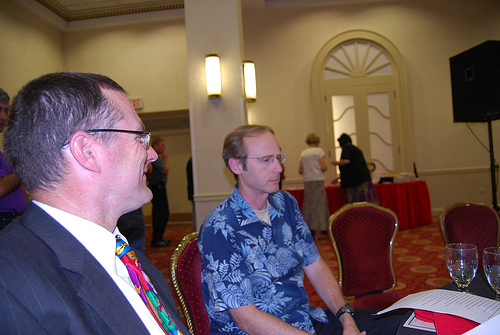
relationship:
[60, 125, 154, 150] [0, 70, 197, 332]
eyeglasses on man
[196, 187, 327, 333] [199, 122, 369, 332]
shirt on man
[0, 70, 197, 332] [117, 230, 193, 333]
man wearing tie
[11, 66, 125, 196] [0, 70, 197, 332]
hair on a man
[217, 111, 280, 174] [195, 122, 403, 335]
hair on a man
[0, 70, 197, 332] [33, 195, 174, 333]
man wearing a shirt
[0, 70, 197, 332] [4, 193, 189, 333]
man wearing a jacket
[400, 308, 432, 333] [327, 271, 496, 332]
paper on a table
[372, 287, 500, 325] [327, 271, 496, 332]
paper on a table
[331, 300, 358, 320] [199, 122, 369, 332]
watch on a man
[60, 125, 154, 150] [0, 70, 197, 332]
eyeglasses on a man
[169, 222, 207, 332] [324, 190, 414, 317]
frame on a chair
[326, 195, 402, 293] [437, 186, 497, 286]
frame on a chair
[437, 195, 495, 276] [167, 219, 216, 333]
frame on a chair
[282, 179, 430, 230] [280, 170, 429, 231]
table cloth on a table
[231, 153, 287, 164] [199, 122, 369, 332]
eyeglasses on a man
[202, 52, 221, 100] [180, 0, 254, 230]
light on a pillar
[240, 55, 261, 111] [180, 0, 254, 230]
light on a pillar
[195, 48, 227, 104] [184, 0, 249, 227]
sconce on a wall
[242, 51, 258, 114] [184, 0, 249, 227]
sconce on a wall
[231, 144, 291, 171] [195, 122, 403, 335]
eyeglasses on a man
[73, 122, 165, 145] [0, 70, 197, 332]
eyeglasses on a man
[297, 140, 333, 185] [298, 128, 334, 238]
shirt on a woman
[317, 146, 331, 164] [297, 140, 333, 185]
sleeve on a shirt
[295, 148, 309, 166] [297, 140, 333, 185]
sleeve on a shirt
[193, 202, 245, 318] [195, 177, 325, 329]
sleeve on a shirt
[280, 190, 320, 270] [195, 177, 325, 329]
sleeve on a shirt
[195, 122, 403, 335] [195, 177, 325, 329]
man wearing a shirt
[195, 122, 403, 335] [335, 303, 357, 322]
man wearing a watch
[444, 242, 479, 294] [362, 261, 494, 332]
glass are on table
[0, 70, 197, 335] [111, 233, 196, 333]
man wearing tie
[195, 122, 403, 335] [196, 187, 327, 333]
man wearing shirt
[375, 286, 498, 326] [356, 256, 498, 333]
paper laying on table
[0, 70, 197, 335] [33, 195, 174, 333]
man wearing shirt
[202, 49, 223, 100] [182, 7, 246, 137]
light hanging on wall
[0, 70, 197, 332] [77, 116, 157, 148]
man has glasses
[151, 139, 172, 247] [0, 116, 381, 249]
man standing in line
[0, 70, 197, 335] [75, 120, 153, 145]
man wearing eyeglasses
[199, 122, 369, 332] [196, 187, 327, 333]
man wearing shirt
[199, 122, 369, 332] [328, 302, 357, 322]
man wearing watch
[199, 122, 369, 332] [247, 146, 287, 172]
man wearing eyeglasses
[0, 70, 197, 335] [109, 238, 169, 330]
man wearing tie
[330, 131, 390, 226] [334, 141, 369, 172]
woman wearing shirt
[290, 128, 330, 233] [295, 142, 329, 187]
woman wearing shirt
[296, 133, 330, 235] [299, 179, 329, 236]
woman wearing skirt